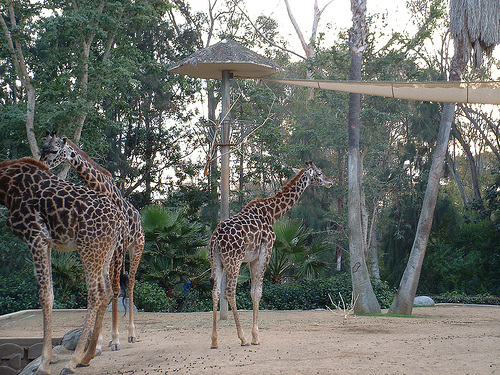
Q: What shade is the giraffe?
A: Brown and beige.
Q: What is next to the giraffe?
A: A tree.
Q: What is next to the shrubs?
A: A tall tree.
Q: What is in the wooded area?
A: Tall trees.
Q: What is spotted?
A: The giraffe.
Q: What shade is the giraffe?
A: Tan and brown.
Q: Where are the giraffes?
A: On the ground.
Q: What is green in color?
A: The leaves.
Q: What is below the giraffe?
A: The dirt.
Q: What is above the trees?
A: The sky.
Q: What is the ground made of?
A: Sand.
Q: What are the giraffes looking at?
A: Different things.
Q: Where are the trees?
A: Around the giraffes.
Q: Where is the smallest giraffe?
A: To the right of the other giraffes.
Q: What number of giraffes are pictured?
A: Three.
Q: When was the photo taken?
A: Day time.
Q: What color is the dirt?
A: Brown.